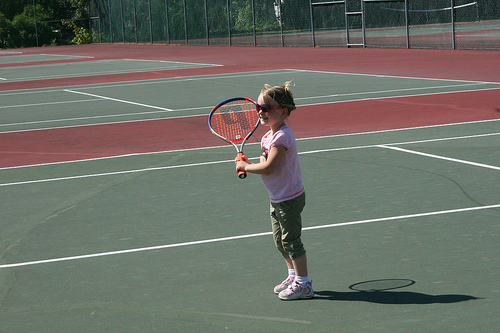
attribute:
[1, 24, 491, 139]
unused courts — unused 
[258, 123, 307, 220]
pink shirt — pink 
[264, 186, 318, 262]
green pants — green 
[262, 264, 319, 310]
shoes — white , pink 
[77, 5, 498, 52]
fence — tall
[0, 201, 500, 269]
line — white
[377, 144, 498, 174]
line — white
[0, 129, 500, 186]
line — white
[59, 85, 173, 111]
line — white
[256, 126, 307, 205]
shirt — pink